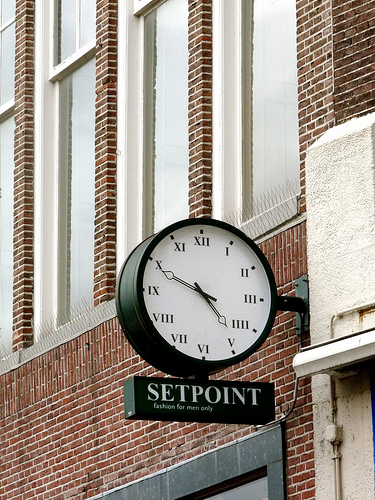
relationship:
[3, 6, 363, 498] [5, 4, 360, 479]
building made bricks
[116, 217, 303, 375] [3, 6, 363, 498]
clock attached building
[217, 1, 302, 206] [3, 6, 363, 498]
window on building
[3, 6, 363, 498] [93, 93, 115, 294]
building made bricks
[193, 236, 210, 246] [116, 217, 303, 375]
roman numberal on clock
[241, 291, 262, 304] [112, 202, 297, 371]
numerals on clock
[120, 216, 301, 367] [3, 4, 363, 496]
clock hanging wall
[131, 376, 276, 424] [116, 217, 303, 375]
sign hanging clock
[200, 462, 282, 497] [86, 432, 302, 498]
glass in on door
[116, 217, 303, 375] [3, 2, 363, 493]
clock mounted on building.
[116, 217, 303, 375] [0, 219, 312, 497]
clock mounted on wall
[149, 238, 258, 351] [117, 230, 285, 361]
numerals on clock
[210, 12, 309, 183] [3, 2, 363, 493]
windows on building.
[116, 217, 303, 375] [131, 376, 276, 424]
clock on sign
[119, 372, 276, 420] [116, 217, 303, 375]
sign below clock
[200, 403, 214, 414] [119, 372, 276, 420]
word on sign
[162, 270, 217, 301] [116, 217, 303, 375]
hand on clock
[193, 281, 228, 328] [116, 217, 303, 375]
hand on clock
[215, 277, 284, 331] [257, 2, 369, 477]
bracket attached to building